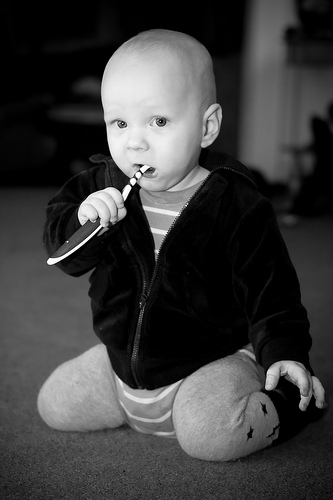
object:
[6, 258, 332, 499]
floor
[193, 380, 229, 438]
gray cloth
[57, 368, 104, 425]
gray cloth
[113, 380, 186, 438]
crotch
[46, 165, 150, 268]
brush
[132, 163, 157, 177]
mouth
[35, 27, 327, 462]
baby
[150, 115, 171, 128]
eye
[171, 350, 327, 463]
thigh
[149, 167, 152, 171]
teeth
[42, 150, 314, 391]
jacket